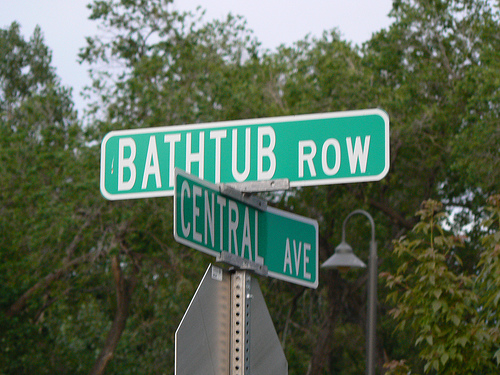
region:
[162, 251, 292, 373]
silver colored back of a stop sign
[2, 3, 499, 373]
green trees behind the sign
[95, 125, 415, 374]
two street signs on top of the pole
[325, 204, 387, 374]
a light pole with a curved top.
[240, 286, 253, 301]
A nut holding the stop sign to the pole/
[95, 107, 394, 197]
Street sign with green background.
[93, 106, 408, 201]
Street sign has words written in white letters.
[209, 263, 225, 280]
White label attached to stop sign.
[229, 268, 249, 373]
Sign post with holes in it.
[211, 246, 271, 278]
grey bracket holding street sign.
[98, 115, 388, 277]
green and white street signs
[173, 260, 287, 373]
stop sign on pole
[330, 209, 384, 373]
grey metal street lamo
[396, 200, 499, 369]
tree with green leaves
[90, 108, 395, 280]
intersection sign on post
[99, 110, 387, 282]
street name signs on post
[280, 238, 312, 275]
avenue name on sign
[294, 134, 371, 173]
row name on sign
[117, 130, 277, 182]
bathtub word on sign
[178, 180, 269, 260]
central word on sign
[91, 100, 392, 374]
three signs attached to pole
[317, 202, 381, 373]
a gray street light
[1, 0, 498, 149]
a gray sky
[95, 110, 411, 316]
two green and white signs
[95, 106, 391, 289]
two signs with white letters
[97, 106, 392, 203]
a sign says BATHTUB ROW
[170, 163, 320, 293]
a sign says CENTRAL AVE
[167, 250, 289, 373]
a backwards silver sign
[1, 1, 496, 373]
trees with green leaves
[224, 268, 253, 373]
a silver sign pole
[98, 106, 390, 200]
a green and white street sign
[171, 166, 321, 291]
a green and white street sign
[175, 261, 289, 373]
back of stop sign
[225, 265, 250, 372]
long metal pole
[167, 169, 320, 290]
CENTRAL AVE street sign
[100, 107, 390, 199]
BATHTUB ROW street sign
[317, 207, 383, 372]
an overhead street light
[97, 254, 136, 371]
a brown tree trunk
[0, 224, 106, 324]
a long tree branch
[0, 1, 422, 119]
a grey sky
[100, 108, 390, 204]
The sign reads Bathtub Row.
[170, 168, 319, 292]
A second sign is below the top one.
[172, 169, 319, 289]
The sign reads Central Ave.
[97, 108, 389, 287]
Two street signs are together.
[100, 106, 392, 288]
The signs are green and white.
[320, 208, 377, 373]
A street light is in the background.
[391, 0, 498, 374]
Trees are in the background.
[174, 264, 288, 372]
A stop sign is under the street signs.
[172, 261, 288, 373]
Only the rear of the stop sign is visible.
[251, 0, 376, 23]
The sky is blue.